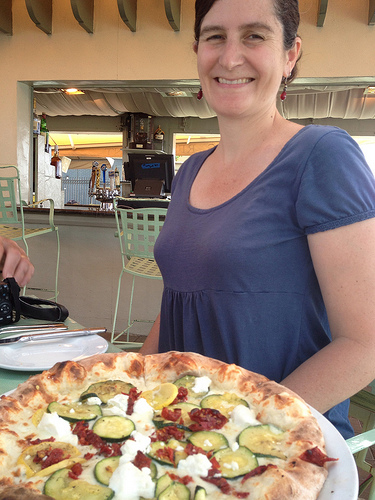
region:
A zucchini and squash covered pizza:
[112, 366, 230, 432]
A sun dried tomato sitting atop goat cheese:
[115, 389, 153, 421]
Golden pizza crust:
[91, 346, 207, 382]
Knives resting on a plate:
[9, 314, 97, 370]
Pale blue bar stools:
[112, 192, 203, 289]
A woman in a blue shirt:
[155, 133, 374, 344]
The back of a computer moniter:
[123, 147, 179, 208]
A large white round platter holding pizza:
[247, 371, 363, 497]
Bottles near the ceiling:
[28, 98, 60, 142]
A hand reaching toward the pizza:
[2, 233, 43, 301]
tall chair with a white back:
[100, 194, 183, 346]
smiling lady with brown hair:
[178, 2, 319, 140]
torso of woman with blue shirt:
[158, 134, 367, 365]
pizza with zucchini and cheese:
[9, 355, 334, 498]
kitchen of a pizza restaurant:
[33, 80, 184, 207]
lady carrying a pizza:
[51, 7, 368, 463]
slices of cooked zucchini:
[55, 390, 133, 447]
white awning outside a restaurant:
[33, 82, 199, 139]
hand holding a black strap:
[4, 238, 69, 334]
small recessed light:
[60, 80, 90, 102]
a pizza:
[2, 353, 358, 498]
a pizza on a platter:
[7, 351, 356, 499]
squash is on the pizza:
[39, 359, 313, 499]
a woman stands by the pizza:
[20, 2, 367, 483]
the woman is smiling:
[150, 1, 366, 436]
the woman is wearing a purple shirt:
[132, 1, 370, 411]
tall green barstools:
[4, 167, 184, 358]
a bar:
[36, 180, 169, 233]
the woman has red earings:
[142, 7, 369, 402]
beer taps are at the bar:
[82, 161, 122, 211]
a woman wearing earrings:
[156, 6, 325, 108]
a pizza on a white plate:
[10, 361, 369, 499]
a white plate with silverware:
[3, 313, 146, 388]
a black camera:
[2, 278, 79, 328]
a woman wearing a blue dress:
[166, 11, 369, 409]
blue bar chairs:
[5, 163, 227, 305]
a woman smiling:
[177, 7, 325, 134]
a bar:
[11, 90, 339, 230]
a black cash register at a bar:
[88, 117, 211, 234]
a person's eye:
[244, 29, 265, 44]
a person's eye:
[205, 30, 226, 45]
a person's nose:
[215, 49, 243, 72]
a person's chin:
[216, 94, 243, 115]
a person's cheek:
[254, 53, 281, 103]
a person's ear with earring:
[277, 37, 300, 108]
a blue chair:
[110, 193, 172, 348]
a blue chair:
[1, 163, 66, 306]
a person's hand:
[1, 235, 33, 283]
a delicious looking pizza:
[0, 343, 338, 496]